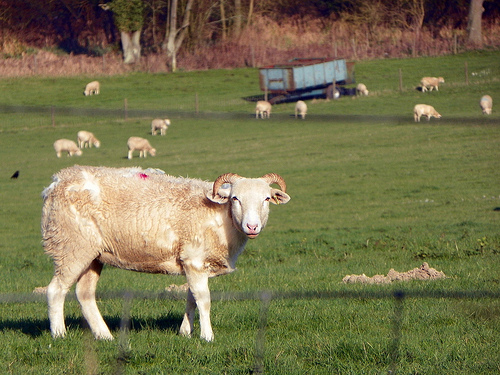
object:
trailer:
[257, 55, 355, 103]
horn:
[262, 173, 286, 192]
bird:
[10, 170, 19, 179]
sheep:
[413, 103, 442, 122]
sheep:
[126, 136, 156, 159]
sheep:
[53, 139, 82, 157]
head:
[205, 172, 292, 238]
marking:
[139, 173, 149, 179]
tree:
[101, 3, 149, 66]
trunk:
[119, 28, 142, 64]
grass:
[1, 46, 500, 373]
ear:
[269, 189, 291, 205]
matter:
[341, 261, 447, 284]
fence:
[1, 58, 497, 131]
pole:
[195, 89, 200, 114]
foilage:
[2, 0, 498, 79]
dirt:
[33, 281, 48, 295]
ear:
[206, 188, 230, 204]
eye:
[265, 197, 272, 202]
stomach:
[100, 244, 183, 276]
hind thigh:
[45, 205, 102, 254]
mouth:
[241, 231, 258, 236]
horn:
[211, 172, 235, 196]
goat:
[37, 164, 289, 342]